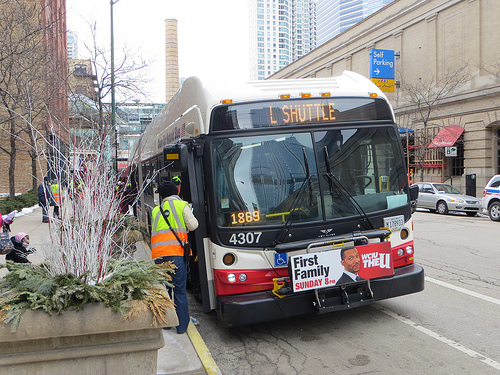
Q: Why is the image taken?
A: Photography.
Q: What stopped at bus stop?
A: Bus.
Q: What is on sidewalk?
A: Planter.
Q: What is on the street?
A: Bus.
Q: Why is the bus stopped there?
A: To allow passengers to board.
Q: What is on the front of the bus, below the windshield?
A: An advertisement for a tv show.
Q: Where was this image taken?
A: At a bus stop.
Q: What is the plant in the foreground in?
A: It is in a concrete planter.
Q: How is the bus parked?
A: It is parallel parked.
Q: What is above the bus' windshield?
A: An electronic sign.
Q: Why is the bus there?
A: To wait for passengers.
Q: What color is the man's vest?
A: Orange and yellow.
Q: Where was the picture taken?
A: In the city.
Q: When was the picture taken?
A: During daytime.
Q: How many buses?
A: One.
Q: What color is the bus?
A: Red and white.